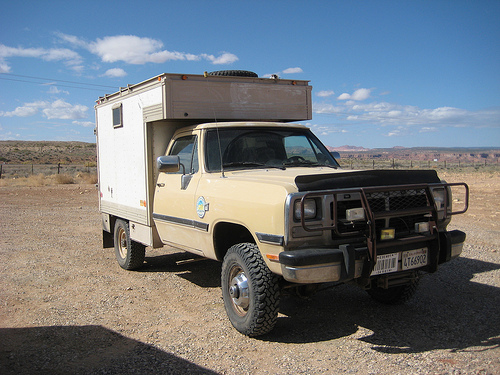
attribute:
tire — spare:
[205, 68, 260, 78]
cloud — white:
[92, 32, 182, 65]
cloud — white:
[0, 42, 46, 57]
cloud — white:
[100, 67, 127, 77]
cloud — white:
[282, 65, 301, 72]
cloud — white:
[210, 51, 239, 65]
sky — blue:
[2, 1, 488, 146]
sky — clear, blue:
[57, 9, 499, 128]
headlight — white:
[292, 198, 321, 220]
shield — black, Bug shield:
[276, 144, 461, 199]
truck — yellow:
[63, 47, 498, 349]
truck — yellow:
[48, 55, 477, 351]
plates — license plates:
[366, 250, 434, 275]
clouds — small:
[331, 83, 499, 140]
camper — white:
[88, 71, 296, 245]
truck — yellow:
[71, 63, 478, 291]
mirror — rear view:
[157, 153, 181, 164]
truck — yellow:
[110, 47, 360, 307]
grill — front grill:
[345, 178, 435, 224]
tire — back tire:
[110, 214, 148, 271]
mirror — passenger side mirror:
[152, 151, 185, 173]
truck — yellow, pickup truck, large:
[92, 64, 470, 334]